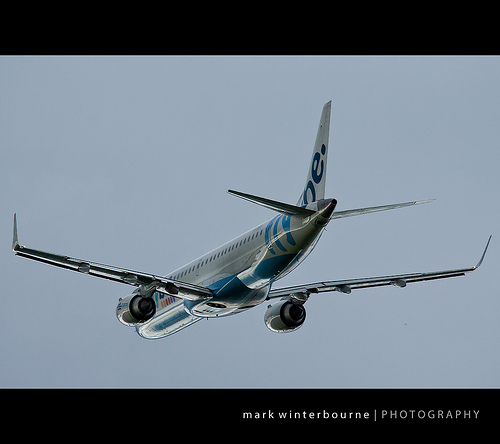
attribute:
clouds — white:
[5, 66, 496, 386]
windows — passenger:
[166, 218, 266, 275]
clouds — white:
[422, 346, 490, 377]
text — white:
[227, 403, 484, 421]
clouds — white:
[319, 335, 482, 385]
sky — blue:
[6, 58, 488, 184]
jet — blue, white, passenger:
[10, 90, 497, 379]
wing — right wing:
[271, 233, 493, 297]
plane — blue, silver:
[1, 78, 498, 370]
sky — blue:
[0, 54, 500, 390]